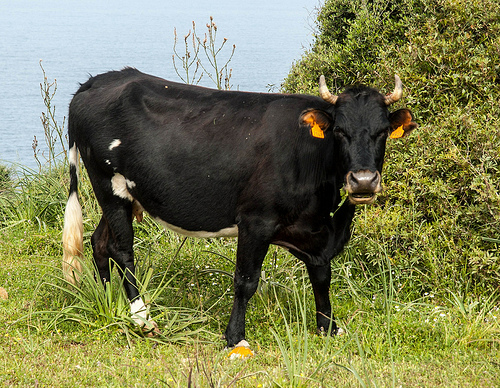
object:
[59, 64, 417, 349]
bull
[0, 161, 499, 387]
grass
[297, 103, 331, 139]
ear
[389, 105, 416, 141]
ear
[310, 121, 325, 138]
id tag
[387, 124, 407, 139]
id tag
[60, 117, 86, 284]
tail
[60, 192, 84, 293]
hair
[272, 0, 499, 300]
tree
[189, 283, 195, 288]
wild flower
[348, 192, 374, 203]
mouth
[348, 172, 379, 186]
nose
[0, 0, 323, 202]
stream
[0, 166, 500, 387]
field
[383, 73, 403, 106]
horn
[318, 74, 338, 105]
horn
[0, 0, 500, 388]
photo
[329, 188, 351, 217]
grass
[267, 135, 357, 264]
chest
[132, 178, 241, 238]
stomach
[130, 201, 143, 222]
udder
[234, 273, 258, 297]
knee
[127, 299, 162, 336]
foot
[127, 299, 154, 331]
spot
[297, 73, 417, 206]
head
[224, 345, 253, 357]
id tag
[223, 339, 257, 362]
hoof